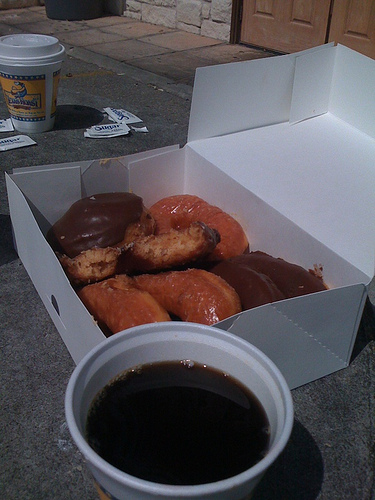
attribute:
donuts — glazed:
[47, 190, 330, 338]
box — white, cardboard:
[4, 39, 373, 388]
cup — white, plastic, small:
[64, 318, 294, 499]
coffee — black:
[86, 360, 269, 486]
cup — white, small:
[0, 34, 66, 133]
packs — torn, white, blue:
[82, 102, 148, 138]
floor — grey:
[0, 1, 374, 498]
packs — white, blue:
[0, 118, 37, 152]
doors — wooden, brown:
[229, 1, 374, 61]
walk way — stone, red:
[1, 1, 290, 99]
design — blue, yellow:
[1, 69, 61, 123]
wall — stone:
[94, 0, 231, 41]